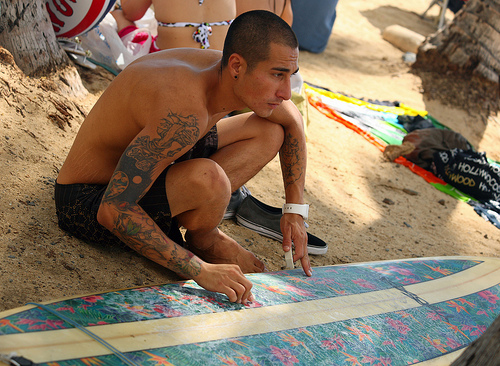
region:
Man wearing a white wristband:
[280, 201, 313, 222]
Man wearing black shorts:
[50, 119, 222, 261]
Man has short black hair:
[220, 8, 300, 80]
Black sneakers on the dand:
[234, 184, 327, 261]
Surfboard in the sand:
[0, 263, 499, 363]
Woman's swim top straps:
[155, 13, 235, 50]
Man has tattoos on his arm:
[93, 110, 206, 281]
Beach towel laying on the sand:
[303, 74, 499, 229]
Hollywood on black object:
[453, 159, 499, 195]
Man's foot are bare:
[181, 226, 266, 275]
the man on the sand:
[37, 13, 333, 299]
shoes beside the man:
[237, 183, 338, 275]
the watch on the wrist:
[280, 195, 327, 223]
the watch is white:
[282, 200, 310, 215]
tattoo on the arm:
[99, 115, 193, 220]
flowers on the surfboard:
[287, 302, 467, 359]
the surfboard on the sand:
[3, 250, 498, 365]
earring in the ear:
[229, 73, 240, 80]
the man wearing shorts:
[40, 7, 338, 285]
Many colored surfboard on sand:
[2, 257, 498, 364]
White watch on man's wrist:
[278, 198, 318, 219]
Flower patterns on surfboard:
[273, 333, 378, 360]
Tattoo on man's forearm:
[282, 127, 300, 196]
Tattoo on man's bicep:
[145, 108, 202, 153]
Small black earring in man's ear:
[232, 70, 238, 80]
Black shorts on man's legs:
[53, 176, 197, 238]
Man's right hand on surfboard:
[200, 260, 260, 299]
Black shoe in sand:
[248, 192, 335, 254]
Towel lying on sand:
[315, 86, 497, 258]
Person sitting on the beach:
[52, 9, 325, 302]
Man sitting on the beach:
[52, 8, 313, 303]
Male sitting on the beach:
[51, 8, 313, 303]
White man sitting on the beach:
[52, 7, 312, 305]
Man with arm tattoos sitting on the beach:
[50, 6, 312, 302]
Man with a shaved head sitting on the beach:
[55, 7, 312, 302]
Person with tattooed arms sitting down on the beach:
[50, 6, 310, 296]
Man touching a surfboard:
[0, 6, 497, 361]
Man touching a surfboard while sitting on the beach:
[0, 5, 490, 356]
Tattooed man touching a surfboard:
[0, 2, 497, 362]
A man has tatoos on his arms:
[102, 110, 305, 277]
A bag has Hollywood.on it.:
[426, 144, 499, 200]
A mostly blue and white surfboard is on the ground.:
[0, 255, 498, 362]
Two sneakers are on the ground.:
[228, 188, 328, 255]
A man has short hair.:
[220, 10, 297, 71]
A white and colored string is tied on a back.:
[153, 0, 239, 53]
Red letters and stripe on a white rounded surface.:
[47, 0, 107, 31]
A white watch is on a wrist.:
[279, 195, 311, 222]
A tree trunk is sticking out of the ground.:
[416, 2, 499, 114]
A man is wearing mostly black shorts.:
[54, 122, 219, 248]